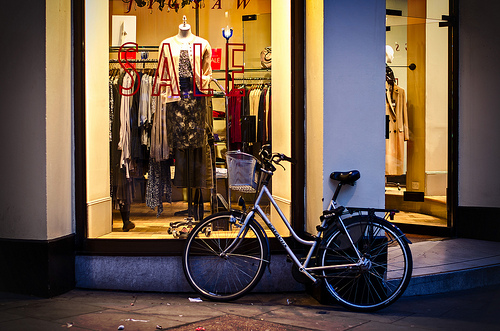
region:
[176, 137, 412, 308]
The bicycle leaning against the wall.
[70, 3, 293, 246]
A store window with clothes on display.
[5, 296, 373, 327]
Slabs of concrete on the sidewalk.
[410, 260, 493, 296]
A step in front of the store.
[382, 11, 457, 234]
The store door is made of glass.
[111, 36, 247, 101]
The word sale is written on the window.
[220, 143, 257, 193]
The bicycle has a basket on the front.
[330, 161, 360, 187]
The bicycle has a black seat.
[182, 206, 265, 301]
The front wheel on the bicycle.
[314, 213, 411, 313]
The back wheel on the bicycle.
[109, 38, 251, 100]
For sale sign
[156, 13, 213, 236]
A mannequin with no head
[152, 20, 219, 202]
Dress for sale, displayed on a mannequin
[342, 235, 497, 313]
Front step of the store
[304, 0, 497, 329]
Store entrance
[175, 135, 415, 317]
Bicycle parked in front of the store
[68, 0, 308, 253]
A display window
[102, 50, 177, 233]
Rack of clothing for sale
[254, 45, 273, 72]
Decorative vase inside the store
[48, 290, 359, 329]
Trash littered on the ground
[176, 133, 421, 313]
a bicycle leaning against a wall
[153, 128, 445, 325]
a bicycle in front of a store window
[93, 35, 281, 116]
a sale decal on a store window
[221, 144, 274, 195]
a bike on the handlebars of a bike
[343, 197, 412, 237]
a rear rack on the back of a bicycle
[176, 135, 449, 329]
a two-wheeled bike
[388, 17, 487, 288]
the porch to a store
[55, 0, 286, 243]
a large glass display of a store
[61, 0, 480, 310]
a bicycle in front of a clothing store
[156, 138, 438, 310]
a silver bike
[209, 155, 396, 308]
bicycle against the wall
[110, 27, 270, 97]
SALE in red on the glass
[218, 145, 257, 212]
basket on the bike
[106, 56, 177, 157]
clothes hanging on the rack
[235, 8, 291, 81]
door to the store is glass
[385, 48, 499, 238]
entrance into the store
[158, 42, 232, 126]
mannequin in the window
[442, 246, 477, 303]
step to go into store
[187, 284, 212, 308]
trash on the ground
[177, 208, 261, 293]
tire on the bike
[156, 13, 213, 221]
mannequin displayed in window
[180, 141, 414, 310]
woman's bicycle leaning against a building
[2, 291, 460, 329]
littered stone pavement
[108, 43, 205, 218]
rack of women's clothing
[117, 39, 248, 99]
The word "sale" printed on the window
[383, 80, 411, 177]
long sleeved tan coat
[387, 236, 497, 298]
stone tiled entryway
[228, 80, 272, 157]
rack of hanging clothes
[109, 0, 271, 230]
softly lit interior of shop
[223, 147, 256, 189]
basket attached to front of bicycle